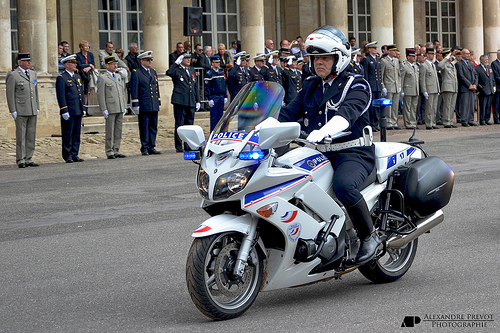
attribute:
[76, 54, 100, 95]
shirt — red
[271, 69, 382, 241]
dress — blue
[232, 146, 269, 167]
light — blue, flashing, led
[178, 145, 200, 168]
light — blue, flashing, led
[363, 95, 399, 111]
light — blue, flashing, led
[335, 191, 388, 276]
boots — black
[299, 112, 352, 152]
glove — white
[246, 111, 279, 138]
glove — white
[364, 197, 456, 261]
exhaust pipe — chrome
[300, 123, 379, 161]
belt — white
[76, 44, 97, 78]
jacket — blue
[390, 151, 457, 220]
box — black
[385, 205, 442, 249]
pipe — chrome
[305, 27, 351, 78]
helmet — white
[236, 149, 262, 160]
light — blue